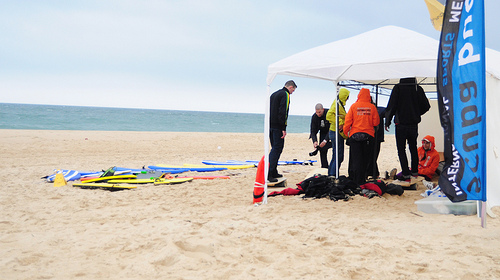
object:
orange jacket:
[418, 135, 441, 180]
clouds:
[76, 65, 235, 106]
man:
[384, 134, 442, 181]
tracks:
[155, 232, 223, 277]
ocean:
[0, 101, 395, 134]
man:
[267, 80, 298, 182]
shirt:
[270, 87, 290, 131]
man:
[308, 103, 332, 168]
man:
[385, 76, 431, 181]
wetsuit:
[307, 108, 330, 143]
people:
[342, 87, 380, 186]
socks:
[308, 148, 318, 157]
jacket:
[325, 87, 350, 139]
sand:
[16, 189, 492, 271]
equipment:
[267, 173, 404, 202]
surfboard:
[267, 176, 287, 187]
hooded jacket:
[343, 87, 380, 138]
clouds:
[23, 14, 161, 49]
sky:
[0, 0, 441, 116]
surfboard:
[202, 160, 251, 165]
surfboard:
[164, 175, 230, 180]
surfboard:
[73, 181, 137, 190]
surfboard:
[245, 158, 318, 166]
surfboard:
[148, 165, 229, 171]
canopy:
[262, 25, 499, 216]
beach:
[0, 129, 499, 280]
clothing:
[385, 77, 431, 124]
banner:
[436, 0, 487, 204]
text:
[460, 80, 481, 193]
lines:
[285, 91, 291, 125]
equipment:
[40, 168, 103, 183]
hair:
[315, 103, 323, 110]